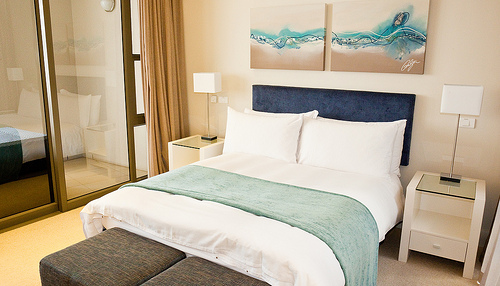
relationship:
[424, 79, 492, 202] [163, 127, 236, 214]
lamp on table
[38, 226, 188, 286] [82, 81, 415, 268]
bench near bed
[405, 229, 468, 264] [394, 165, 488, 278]
drawer on a table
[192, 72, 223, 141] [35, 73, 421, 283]
lamp on side of bed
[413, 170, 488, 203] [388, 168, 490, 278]
table top on stand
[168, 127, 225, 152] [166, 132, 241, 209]
table top on stand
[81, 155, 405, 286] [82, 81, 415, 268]
blanket on top of bed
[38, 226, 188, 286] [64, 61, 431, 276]
bench at foot of bed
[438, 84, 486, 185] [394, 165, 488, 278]
lamp on right table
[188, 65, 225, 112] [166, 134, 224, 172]
lamp on left stand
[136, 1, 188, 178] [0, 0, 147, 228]
beige curtain over windows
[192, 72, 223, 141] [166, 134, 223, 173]
lamp on night stand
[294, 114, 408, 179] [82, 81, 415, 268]
pillow on bed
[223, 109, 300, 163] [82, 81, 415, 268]
pillow on bed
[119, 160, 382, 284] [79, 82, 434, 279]
blanket draped over bed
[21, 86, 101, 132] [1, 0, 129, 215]
pillows reflected on glass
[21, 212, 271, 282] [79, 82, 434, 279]
bench at end of bed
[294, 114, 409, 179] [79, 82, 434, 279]
pillow on bed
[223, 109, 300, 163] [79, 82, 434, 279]
pillow on bed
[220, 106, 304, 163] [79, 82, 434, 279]
pillow on bed